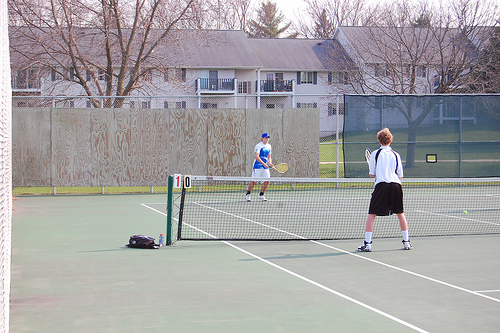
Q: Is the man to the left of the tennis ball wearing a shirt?
A: Yes, the man is wearing a shirt.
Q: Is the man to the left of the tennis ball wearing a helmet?
A: No, the man is wearing a shirt.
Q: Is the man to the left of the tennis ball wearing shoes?
A: Yes, the man is wearing shoes.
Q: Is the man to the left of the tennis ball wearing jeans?
A: No, the man is wearing shoes.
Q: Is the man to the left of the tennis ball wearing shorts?
A: Yes, the man is wearing shorts.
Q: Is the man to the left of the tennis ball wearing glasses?
A: No, the man is wearing shorts.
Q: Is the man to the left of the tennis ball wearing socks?
A: Yes, the man is wearing socks.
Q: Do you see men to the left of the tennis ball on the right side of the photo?
A: Yes, there is a man to the left of the tennis ball.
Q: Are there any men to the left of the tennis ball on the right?
A: Yes, there is a man to the left of the tennis ball.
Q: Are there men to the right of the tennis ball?
A: No, the man is to the left of the tennis ball.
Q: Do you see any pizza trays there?
A: No, there are no pizza trays.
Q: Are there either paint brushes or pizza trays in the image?
A: No, there are no pizza trays or paint brushes.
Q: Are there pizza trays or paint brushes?
A: No, there are no pizza trays or paint brushes.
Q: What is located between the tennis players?
A: The net is between the players.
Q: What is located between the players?
A: The net is between the players.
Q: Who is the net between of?
A: The net is between the players.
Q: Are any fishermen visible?
A: No, there are no fishermen.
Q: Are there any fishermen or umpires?
A: No, there are no fishermen or umpires.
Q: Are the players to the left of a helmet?
A: No, the players are to the left of the tennis ball.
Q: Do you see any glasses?
A: No, there are no glasses.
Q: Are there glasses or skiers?
A: No, there are no glasses or skiers.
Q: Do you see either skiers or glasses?
A: No, there are no glasses or skiers.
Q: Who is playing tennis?
A: The man is playing tennis.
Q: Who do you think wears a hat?
A: The man wears a hat.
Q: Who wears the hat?
A: The man wears a hat.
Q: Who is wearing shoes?
A: The man is wearing shoes.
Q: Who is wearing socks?
A: The man is wearing socks.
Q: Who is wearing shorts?
A: The man is wearing shorts.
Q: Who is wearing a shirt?
A: The man is wearing a shirt.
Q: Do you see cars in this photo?
A: No, there are no cars.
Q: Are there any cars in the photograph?
A: No, there are no cars.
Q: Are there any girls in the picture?
A: No, there are no girls.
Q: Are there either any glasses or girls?
A: No, there are no girls or glasses.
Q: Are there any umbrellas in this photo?
A: No, there are no umbrellas.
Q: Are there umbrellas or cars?
A: No, there are no umbrellas or cars.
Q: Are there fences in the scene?
A: Yes, there is a fence.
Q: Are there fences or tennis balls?
A: Yes, there is a fence.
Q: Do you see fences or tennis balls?
A: Yes, there is a fence.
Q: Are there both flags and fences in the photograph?
A: No, there is a fence but no flags.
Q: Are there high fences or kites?
A: Yes, there is a high fence.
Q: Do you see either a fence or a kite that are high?
A: Yes, the fence is high.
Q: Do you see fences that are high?
A: Yes, there is a high fence.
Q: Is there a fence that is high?
A: Yes, there is a fence that is high.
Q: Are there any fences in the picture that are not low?
A: Yes, there is a high fence.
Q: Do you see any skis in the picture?
A: No, there are no skis.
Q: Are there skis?
A: No, there are no skis.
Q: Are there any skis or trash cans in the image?
A: No, there are no skis or trash cans.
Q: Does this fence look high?
A: Yes, the fence is high.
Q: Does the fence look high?
A: Yes, the fence is high.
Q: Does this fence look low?
A: No, the fence is high.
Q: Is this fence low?
A: No, the fence is high.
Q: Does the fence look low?
A: No, the fence is high.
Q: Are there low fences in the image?
A: No, there is a fence but it is high.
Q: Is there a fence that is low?
A: No, there is a fence but it is high.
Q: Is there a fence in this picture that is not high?
A: No, there is a fence but it is high.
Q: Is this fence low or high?
A: The fence is high.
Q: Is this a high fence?
A: Yes, this is a high fence.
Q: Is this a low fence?
A: No, this is a high fence.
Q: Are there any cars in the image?
A: No, there are no cars.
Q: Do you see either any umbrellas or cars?
A: No, there are no cars or umbrellas.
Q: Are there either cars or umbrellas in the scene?
A: No, there are no cars or umbrellas.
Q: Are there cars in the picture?
A: No, there are no cars.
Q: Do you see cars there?
A: No, there are no cars.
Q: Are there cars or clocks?
A: No, there are no cars or clocks.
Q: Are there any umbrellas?
A: No, there are no umbrellas.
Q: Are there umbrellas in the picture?
A: No, there are no umbrellas.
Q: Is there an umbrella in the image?
A: No, there are no umbrellas.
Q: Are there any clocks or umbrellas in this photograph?
A: No, there are no umbrellas or clocks.